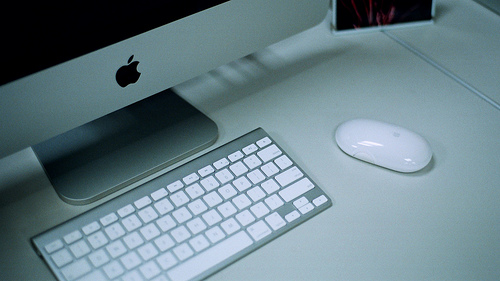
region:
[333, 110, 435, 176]
White mouse on the desk.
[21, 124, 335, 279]
Keyboard on the desk.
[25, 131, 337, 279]
white buttons on the keyboard.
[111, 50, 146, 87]
Apple logo on the computer.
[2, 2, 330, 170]
Monitor on the desk.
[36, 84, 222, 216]
Silver leg on the monitor.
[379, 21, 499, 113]
white cord on the desk.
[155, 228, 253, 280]
Space bar on the keyboard.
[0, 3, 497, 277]
White desk in the forefront.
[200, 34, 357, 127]
shadow on the desk.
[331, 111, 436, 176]
sleek white computer mouse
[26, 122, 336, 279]
gray keyboard with white buttons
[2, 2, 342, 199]
apple computer monitor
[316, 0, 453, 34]
card on top of desk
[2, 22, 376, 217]
shadow cast by the monitor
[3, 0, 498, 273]
white desk with computer on it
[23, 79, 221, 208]
monitor stand is gray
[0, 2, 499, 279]
Desk with Apple brand computer on it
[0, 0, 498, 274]
Apple computer sitting on a white desk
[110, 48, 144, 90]
Apple Mac logo on desktop monitor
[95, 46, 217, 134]
the apple logo is black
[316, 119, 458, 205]
the mouse is wireless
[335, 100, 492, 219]
the mouse is white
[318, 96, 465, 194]
the mouse is glossy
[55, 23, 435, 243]
an apple desktop setup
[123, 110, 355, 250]
the keys are white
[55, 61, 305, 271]
the keyboard is brushed silver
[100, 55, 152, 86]
this is a logo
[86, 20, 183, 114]
the apple logo is black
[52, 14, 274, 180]
this is the monitor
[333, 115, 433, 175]
A white cordless mouse.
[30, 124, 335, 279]
A silver and white keyboard.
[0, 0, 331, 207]
An apple brand monitor.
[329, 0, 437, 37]
A black picture in a frame.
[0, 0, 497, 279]
A white desktop.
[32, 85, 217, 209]
A gray monitor stand.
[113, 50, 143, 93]
A black apple logo.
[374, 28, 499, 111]
A white wire.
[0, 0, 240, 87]
A dark monitor screen.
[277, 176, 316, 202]
A white keyboard key.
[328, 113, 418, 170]
a white wireless mouse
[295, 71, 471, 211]
a white wireless mouse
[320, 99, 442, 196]
a white wireless mouse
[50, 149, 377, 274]
the keyboard is white